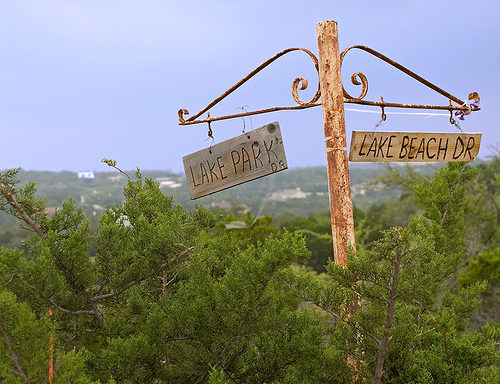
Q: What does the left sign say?
A: Lake Park.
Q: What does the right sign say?
A: Lake Beach Dr.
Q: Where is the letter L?
A: On the sign.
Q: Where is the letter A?
A: On the sign.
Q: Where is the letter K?
A: On the sign.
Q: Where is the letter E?
A: On the sign.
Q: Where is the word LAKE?
A: On the sign.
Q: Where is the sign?
A: On the post.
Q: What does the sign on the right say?
A: Lake beach dr.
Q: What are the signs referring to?
A: Streets.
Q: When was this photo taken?
A: During daylight hours.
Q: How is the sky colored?
A: Blue.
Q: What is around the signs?
A: Evergreens.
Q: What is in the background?
A: A town.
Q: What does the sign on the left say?
A: Lake park dr.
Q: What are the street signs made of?
A: Wood.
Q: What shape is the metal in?
A: Rusty.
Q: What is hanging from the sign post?
A: Wooden signs.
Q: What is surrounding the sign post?
A: Trees.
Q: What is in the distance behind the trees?
A: Buildings.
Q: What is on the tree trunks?
A: Green leaves.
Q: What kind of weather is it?
A: Clear and sunny.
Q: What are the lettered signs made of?
A: Wood.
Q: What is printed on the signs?
A: Street names.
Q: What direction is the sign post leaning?
A: Left.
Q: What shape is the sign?
A: Rectangular.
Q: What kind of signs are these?
A: Street.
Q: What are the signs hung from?
A: Post.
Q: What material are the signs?
A: Wooden.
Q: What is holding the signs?
A: Metal brackets.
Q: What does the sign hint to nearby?
A: Lake.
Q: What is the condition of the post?
A: Rusty.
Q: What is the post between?
A: Trees.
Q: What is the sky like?
A: Clear.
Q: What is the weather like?
A: Sunny.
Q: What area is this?
A: Countryside.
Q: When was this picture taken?
A: Daytime.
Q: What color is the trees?
A: Green.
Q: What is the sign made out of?
A: Wood.